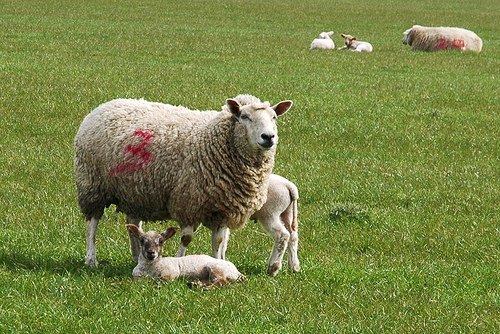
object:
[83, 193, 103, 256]
legs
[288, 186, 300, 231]
tail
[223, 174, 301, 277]
animal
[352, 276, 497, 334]
green grass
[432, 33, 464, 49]
letter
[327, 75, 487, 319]
clean grass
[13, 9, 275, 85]
clean grass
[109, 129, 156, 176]
letter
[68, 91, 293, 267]
sheep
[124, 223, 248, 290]
baby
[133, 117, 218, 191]
wool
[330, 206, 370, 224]
letter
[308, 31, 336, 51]
lamb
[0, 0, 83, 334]
grass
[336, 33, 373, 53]
lambs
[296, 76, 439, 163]
grass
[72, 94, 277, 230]
coat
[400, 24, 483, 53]
ewe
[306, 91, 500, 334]
ground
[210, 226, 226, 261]
legs